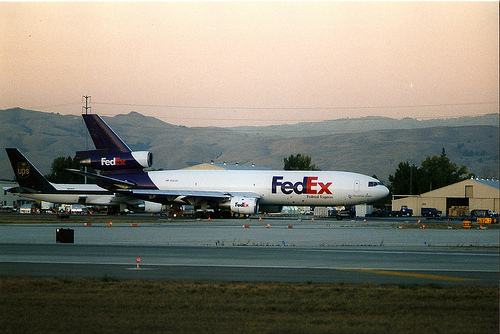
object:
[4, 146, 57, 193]
wing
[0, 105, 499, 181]
mountains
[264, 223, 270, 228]
cones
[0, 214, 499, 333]
ground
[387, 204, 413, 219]
truck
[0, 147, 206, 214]
airplane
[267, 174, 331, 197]
name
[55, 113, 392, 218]
aircraft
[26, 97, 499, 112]
electric lines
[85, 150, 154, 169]
engine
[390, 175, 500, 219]
building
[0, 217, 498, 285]
runway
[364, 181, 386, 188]
cockpit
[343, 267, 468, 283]
line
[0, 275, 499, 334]
grass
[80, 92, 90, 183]
pole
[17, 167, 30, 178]
"ups"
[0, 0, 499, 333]
background